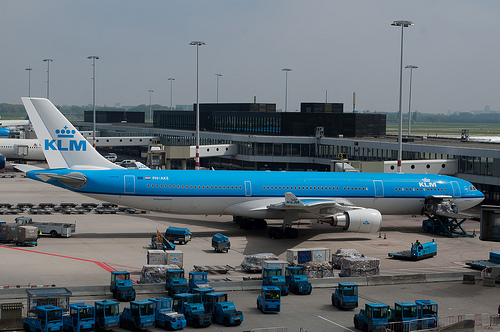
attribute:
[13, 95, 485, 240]
plane — blue, white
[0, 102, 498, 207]
terminal — large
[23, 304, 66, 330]
cart — blue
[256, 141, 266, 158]
window — glass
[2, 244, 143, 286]
paint — red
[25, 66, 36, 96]
light post — tall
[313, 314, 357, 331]
paint — white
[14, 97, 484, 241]
airplane — blue, white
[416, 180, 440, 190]
airline name — white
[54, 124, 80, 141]
crown — blue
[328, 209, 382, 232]
engine — large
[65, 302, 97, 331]
cart vehicle — blue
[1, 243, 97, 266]
line — red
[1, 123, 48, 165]
airplane — in the background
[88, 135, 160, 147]
hallway — for boarding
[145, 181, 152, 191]
window — small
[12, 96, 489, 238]
airliner — large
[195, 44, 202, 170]
mast — tall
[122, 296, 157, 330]
utility truck — blue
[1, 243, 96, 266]
marking — red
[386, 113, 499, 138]
vegetation — distant